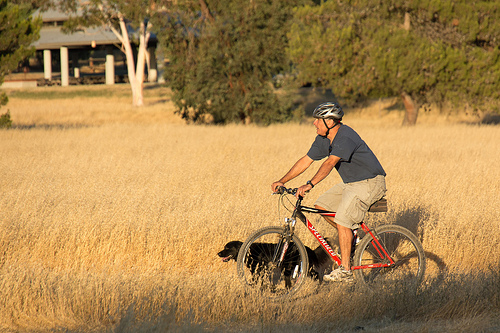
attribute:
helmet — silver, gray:
[311, 100, 346, 122]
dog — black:
[217, 240, 332, 287]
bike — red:
[234, 182, 427, 298]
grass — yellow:
[3, 94, 499, 331]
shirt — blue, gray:
[306, 124, 388, 186]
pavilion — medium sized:
[33, 26, 167, 90]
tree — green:
[283, 3, 499, 124]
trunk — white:
[97, 3, 161, 109]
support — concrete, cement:
[59, 45, 71, 91]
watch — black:
[305, 179, 317, 191]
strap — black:
[322, 116, 339, 139]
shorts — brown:
[312, 172, 388, 230]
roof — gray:
[26, 28, 142, 42]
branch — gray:
[95, 2, 127, 58]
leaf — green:
[398, 50, 413, 59]